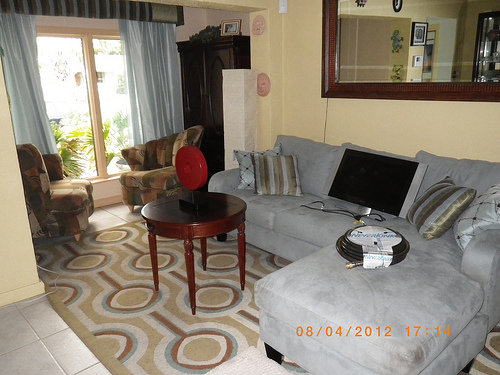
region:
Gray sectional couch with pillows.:
[206, 128, 491, 365]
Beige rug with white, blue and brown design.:
[34, 227, 276, 373]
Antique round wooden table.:
[141, 196, 258, 314]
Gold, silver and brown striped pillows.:
[252, 152, 480, 240]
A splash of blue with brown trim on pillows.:
[225, 144, 495, 251]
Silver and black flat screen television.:
[322, 140, 434, 225]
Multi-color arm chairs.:
[16, 128, 205, 253]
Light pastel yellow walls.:
[184, 3, 496, 161]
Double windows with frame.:
[28, 23, 158, 191]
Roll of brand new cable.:
[336, 222, 413, 275]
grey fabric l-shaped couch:
[209, 133, 498, 373]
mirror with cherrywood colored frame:
[321, 0, 498, 102]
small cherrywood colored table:
[141, 190, 247, 314]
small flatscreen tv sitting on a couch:
[318, 141, 428, 229]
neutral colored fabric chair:
[119, 124, 205, 211]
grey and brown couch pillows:
[233, 143, 304, 197]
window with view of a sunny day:
[35, 36, 138, 174]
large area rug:
[28, 213, 294, 373]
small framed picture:
[218, 17, 242, 35]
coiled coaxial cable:
[334, 223, 410, 272]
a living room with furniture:
[39, 37, 497, 374]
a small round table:
[136, 185, 256, 316]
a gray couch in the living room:
[221, 139, 326, 237]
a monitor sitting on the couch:
[321, 139, 430, 224]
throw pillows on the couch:
[239, 145, 304, 202]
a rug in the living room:
[58, 293, 145, 370]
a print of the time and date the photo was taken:
[288, 319, 454, 346]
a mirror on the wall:
[303, 17, 436, 125]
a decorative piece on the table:
[162, 145, 217, 218]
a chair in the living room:
[110, 118, 155, 213]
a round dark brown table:
[139, 192, 247, 314]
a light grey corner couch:
[210, 131, 495, 368]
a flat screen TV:
[327, 147, 419, 222]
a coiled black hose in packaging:
[334, 224, 409, 271]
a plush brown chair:
[13, 143, 93, 241]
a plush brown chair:
[116, 126, 202, 198]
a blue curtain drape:
[122, 17, 184, 147]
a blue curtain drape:
[0, 15, 58, 158]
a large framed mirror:
[319, 0, 497, 102]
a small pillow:
[247, 148, 299, 199]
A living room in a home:
[14, 10, 489, 361]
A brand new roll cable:
[333, 217, 421, 278]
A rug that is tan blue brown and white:
[87, 292, 250, 372]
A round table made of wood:
[133, 195, 255, 315]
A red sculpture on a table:
[165, 148, 213, 223]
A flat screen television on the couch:
[310, 142, 433, 228]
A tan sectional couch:
[288, 138, 474, 363]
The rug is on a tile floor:
[14, 290, 114, 362]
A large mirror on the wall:
[297, 8, 495, 123]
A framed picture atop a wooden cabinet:
[214, 12, 245, 39]